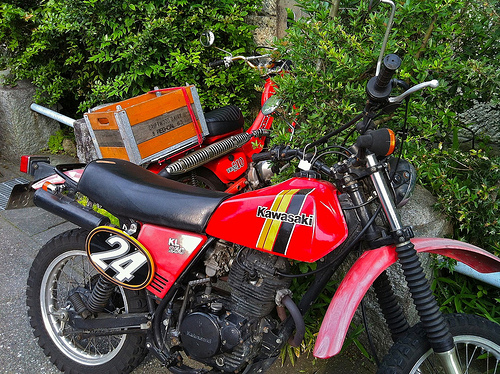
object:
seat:
[204, 105, 248, 137]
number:
[109, 249, 148, 282]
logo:
[81, 222, 158, 291]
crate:
[81, 84, 212, 167]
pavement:
[0, 166, 366, 373]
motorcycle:
[0, 55, 500, 374]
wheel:
[375, 311, 500, 374]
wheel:
[21, 226, 151, 374]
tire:
[26, 228, 148, 372]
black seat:
[74, 155, 232, 238]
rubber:
[365, 52, 403, 105]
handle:
[365, 53, 403, 105]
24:
[89, 235, 149, 282]